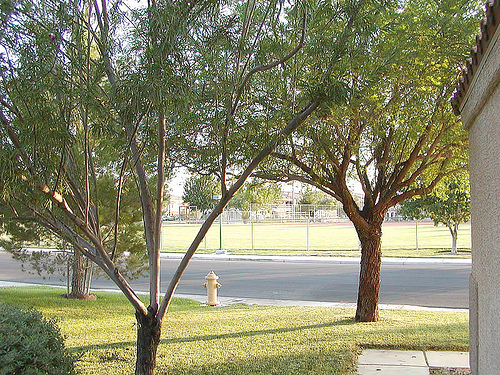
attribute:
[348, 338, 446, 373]
path — paved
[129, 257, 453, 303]
surface — road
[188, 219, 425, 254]
fence — metallic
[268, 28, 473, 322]
tree — one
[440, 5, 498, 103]
roof — brick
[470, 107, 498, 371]
wall — concrete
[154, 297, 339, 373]
field — grassy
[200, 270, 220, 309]
hydrant — water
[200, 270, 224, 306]
hydrant — metallic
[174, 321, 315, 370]
grass — green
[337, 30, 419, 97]
leaves — green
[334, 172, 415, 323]
tree — woody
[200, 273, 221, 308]
hydrant — white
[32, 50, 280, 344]
tree — branchy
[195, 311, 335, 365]
grass — short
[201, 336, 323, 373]
grass — green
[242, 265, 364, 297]
road — paved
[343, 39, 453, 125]
leaves — green